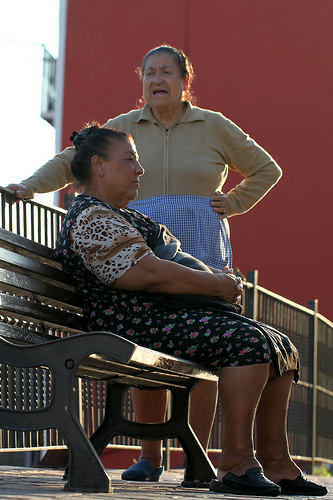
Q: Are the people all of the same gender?
A: Yes, all the people are female.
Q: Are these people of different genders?
A: No, all the people are female.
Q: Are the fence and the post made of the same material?
A: Yes, both the fence and the post are made of metal.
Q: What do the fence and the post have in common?
A: The material, both the fence and the post are metallic.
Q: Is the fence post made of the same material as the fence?
A: Yes, both the post and the fence are made of metal.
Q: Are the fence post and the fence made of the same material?
A: Yes, both the post and the fence are made of metal.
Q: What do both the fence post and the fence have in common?
A: The material, both the post and the fence are metallic.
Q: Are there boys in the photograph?
A: No, there are no boys.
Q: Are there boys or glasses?
A: No, there are no boys or glasses.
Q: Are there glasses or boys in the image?
A: No, there are no boys or glasses.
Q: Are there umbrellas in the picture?
A: No, there are no umbrellas.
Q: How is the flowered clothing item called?
A: The clothing item is a dress.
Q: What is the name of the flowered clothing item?
A: The clothing item is a dress.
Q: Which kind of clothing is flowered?
A: The clothing is a dress.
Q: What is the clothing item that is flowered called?
A: The clothing item is a dress.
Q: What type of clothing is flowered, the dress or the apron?
A: The dress is flowered.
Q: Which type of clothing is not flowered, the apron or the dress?
A: The apron is not flowered.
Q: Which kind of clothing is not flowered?
A: The clothing is an apron.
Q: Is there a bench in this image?
A: Yes, there is a bench.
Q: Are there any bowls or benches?
A: Yes, there is a bench.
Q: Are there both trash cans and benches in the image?
A: No, there is a bench but no trash cans.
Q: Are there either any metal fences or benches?
A: Yes, there is a metal bench.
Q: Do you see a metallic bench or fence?
A: Yes, there is a metal bench.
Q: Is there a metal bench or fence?
A: Yes, there is a metal bench.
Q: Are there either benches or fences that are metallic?
A: Yes, the bench is metallic.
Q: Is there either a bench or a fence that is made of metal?
A: Yes, the bench is made of metal.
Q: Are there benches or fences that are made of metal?
A: Yes, the bench is made of metal.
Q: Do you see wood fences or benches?
A: Yes, there is a wood bench.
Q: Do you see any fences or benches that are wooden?
A: Yes, the bench is wooden.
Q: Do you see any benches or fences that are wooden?
A: Yes, the bench is wooden.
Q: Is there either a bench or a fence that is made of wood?
A: Yes, the bench is made of wood.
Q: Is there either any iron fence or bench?
A: Yes, there is an iron bench.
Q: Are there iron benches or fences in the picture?
A: Yes, there is an iron bench.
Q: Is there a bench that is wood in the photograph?
A: Yes, there is a wood bench.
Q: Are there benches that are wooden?
A: Yes, there is a bench that is wooden.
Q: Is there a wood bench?
A: Yes, there is a bench that is made of wood.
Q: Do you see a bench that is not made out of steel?
A: Yes, there is a bench that is made of wood.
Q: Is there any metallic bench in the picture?
A: Yes, there is a metal bench.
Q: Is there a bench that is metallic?
A: Yes, there is a bench that is metallic.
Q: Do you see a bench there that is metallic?
A: Yes, there is a bench that is metallic.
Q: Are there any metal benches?
A: Yes, there is a bench that is made of metal.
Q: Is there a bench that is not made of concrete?
A: Yes, there is a bench that is made of metal.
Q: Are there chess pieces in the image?
A: No, there are no chess pieces.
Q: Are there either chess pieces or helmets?
A: No, there are no chess pieces or helmets.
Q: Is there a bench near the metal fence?
A: Yes, there is a bench near the fence.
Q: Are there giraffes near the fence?
A: No, there is a bench near the fence.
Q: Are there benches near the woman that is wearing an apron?
A: Yes, there is a bench near the woman.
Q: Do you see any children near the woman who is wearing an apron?
A: No, there is a bench near the woman.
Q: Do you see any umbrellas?
A: No, there are no umbrellas.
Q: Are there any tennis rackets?
A: No, there are no tennis rackets.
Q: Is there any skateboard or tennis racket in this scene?
A: No, there are no rackets or skateboards.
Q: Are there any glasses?
A: No, there are no glasses.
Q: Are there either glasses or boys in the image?
A: No, there are no glasses or boys.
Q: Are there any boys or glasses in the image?
A: No, there are no glasses or boys.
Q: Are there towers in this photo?
A: No, there are no towers.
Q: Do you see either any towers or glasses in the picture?
A: No, there are no towers or glasses.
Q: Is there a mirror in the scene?
A: No, there are no mirrors.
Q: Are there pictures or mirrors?
A: No, there are no mirrors or pictures.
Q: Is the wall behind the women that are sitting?
A: Yes, the wall is behind the women.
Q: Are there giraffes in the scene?
A: No, there are no giraffes.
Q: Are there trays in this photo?
A: No, there are no trays.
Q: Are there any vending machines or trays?
A: No, there are no trays or vending machines.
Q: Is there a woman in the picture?
A: Yes, there is a woman.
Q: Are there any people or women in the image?
A: Yes, there is a woman.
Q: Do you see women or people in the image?
A: Yes, there is a woman.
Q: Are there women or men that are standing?
A: Yes, the woman is standing.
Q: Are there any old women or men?
A: Yes, there is an old woman.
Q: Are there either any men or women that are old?
A: Yes, the woman is old.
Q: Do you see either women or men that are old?
A: Yes, the woman is old.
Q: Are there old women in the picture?
A: Yes, there is an old woman.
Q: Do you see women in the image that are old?
A: Yes, there is a woman that is old.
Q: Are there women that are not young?
A: Yes, there is a old woman.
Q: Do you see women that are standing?
A: Yes, there is a woman that is standing.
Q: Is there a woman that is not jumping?
A: Yes, there is a woman that is standing.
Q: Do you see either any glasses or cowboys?
A: No, there are no glasses or cowboys.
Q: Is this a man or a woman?
A: This is a woman.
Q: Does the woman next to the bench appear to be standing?
A: Yes, the woman is standing.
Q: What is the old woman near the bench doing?
A: The woman is standing.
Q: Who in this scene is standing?
A: The woman is standing.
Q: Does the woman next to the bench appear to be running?
A: No, the woman is standing.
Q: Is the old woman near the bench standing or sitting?
A: The woman is standing.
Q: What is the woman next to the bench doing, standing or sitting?
A: The woman is standing.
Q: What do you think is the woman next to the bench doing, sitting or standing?
A: The woman is standing.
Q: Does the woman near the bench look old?
A: Yes, the woman is old.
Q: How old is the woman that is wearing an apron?
A: The woman is old.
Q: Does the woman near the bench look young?
A: No, the woman is old.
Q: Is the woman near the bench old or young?
A: The woman is old.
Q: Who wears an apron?
A: The woman wears an apron.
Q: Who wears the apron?
A: The woman wears an apron.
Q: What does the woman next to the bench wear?
A: The woman wears an apron.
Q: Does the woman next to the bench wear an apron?
A: Yes, the woman wears an apron.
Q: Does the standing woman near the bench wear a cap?
A: No, the woman wears an apron.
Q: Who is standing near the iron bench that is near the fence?
A: The woman is standing near the bench.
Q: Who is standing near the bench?
A: The woman is standing near the bench.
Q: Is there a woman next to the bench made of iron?
A: Yes, there is a woman next to the bench.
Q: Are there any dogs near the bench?
A: No, there is a woman near the bench.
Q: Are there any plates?
A: No, there are no plates.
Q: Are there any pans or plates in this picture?
A: No, there are no plates or pans.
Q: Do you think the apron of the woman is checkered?
A: Yes, the apron is checkered.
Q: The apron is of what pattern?
A: The apron is checkered.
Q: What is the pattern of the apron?
A: The apron is checkered.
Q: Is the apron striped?
A: No, the apron is checkered.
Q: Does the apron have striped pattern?
A: No, the apron is checkered.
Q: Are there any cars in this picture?
A: No, there are no cars.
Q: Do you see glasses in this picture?
A: No, there are no glasses.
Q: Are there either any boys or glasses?
A: No, there are no glasses or boys.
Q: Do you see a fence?
A: Yes, there is a fence.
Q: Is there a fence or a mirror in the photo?
A: Yes, there is a fence.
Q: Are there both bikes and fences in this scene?
A: No, there is a fence but no bikes.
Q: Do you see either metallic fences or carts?
A: Yes, there is a metal fence.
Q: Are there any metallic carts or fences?
A: Yes, there is a metal fence.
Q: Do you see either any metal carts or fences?
A: Yes, there is a metal fence.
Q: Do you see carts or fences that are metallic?
A: Yes, the fence is metallic.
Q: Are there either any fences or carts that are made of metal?
A: Yes, the fence is made of metal.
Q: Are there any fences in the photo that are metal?
A: Yes, there is a metal fence.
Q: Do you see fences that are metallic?
A: Yes, there is a fence that is metallic.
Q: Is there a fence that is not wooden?
A: Yes, there is a metallic fence.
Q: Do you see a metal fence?
A: Yes, there is a fence that is made of metal.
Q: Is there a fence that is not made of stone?
A: Yes, there is a fence that is made of metal.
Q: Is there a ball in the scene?
A: No, there are no balls.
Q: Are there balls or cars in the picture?
A: No, there are no balls or cars.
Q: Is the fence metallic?
A: Yes, the fence is metallic.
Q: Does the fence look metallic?
A: Yes, the fence is metallic.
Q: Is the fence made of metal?
A: Yes, the fence is made of metal.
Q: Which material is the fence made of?
A: The fence is made of metal.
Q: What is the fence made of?
A: The fence is made of metal.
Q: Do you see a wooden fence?
A: No, there is a fence but it is metallic.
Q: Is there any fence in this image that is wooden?
A: No, there is a fence but it is metallic.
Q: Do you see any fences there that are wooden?
A: No, there is a fence but it is metallic.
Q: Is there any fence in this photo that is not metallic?
A: No, there is a fence but it is metallic.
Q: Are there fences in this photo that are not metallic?
A: No, there is a fence but it is metallic.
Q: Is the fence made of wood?
A: No, the fence is made of metal.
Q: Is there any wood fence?
A: No, there is a fence but it is made of metal.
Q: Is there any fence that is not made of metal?
A: No, there is a fence but it is made of metal.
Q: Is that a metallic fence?
A: Yes, that is a metallic fence.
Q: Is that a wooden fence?
A: No, that is a metallic fence.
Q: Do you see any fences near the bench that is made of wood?
A: Yes, there is a fence near the bench.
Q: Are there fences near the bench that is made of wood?
A: Yes, there is a fence near the bench.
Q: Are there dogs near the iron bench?
A: No, there is a fence near the bench.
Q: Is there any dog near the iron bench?
A: No, there is a fence near the bench.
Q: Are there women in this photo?
A: Yes, there are women.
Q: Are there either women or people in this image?
A: Yes, there are women.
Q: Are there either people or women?
A: Yes, there are women.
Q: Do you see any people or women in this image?
A: Yes, there are women.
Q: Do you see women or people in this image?
A: Yes, there are women.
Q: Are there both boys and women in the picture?
A: No, there are women but no boys.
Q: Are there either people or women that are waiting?
A: Yes, the women are waiting.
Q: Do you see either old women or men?
A: Yes, there are old women.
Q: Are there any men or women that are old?
A: Yes, the women are old.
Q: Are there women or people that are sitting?
A: Yes, the women are sitting.